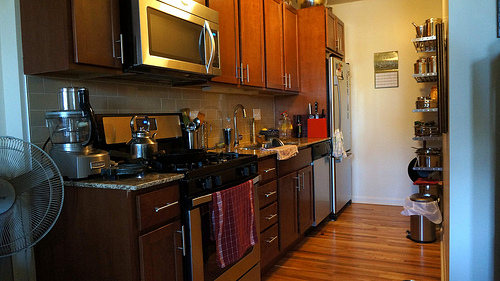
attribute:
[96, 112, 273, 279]
oven — gas burning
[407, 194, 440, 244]
trash can — steel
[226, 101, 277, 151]
faucet — curved, grey, metal, sink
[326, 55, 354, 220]
refrigerator — grey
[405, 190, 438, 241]
trash bin — metal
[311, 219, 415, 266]
panels — wooden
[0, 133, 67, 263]
fan — round, electric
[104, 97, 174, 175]
kettle — grey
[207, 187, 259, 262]
dish towel — Red , plaid , hanging 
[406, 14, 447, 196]
pantry — filled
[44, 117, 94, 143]
bowl — clear